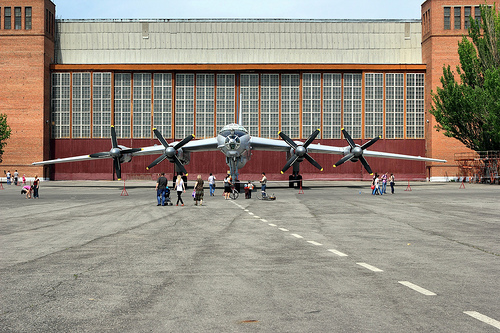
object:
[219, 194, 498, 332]
lines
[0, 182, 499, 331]
asphalt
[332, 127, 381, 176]
prop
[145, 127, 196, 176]
prop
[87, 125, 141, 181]
prop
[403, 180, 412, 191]
safety triangle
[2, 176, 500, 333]
ground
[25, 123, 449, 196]
plane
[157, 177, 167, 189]
black shirt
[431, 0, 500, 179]
tree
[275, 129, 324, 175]
propeller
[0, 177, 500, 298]
dash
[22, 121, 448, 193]
jet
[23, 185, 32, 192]
shirt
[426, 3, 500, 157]
leaves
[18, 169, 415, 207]
people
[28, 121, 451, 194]
prop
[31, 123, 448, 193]
display